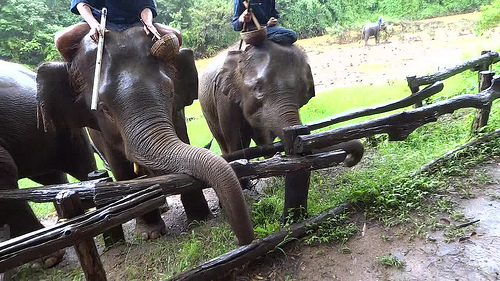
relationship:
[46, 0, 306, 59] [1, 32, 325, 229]
people riding elephants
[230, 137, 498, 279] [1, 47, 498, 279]
bare ground near fence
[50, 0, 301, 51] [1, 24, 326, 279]
people riding elephants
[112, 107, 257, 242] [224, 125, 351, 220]
trunk on fence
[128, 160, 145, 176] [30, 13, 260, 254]
tusk on elephant